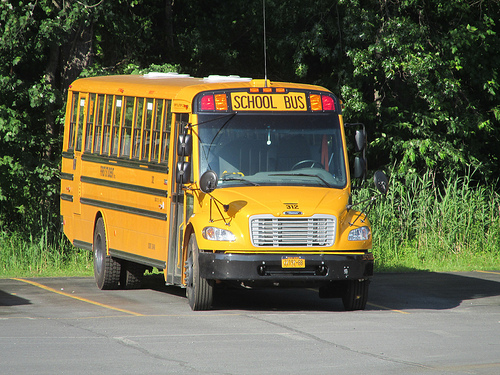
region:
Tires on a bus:
[84, 198, 142, 314]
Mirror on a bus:
[183, 161, 258, 227]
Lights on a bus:
[192, 78, 237, 126]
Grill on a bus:
[241, 203, 346, 263]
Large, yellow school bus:
[52, 65, 408, 324]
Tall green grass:
[358, 172, 494, 285]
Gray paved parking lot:
[34, 277, 249, 368]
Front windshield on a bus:
[193, 92, 374, 205]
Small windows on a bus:
[59, 76, 180, 171]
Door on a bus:
[163, 104, 203, 277]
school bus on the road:
[56, 60, 386, 317]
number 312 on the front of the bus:
[284, 202, 306, 212]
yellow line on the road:
[7, 272, 151, 324]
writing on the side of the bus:
[98, 160, 125, 180]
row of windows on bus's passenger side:
[67, 88, 177, 169]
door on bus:
[171, 108, 193, 291]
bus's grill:
[251, 209, 339, 251]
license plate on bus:
[278, 252, 308, 272]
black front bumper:
[195, 247, 379, 292]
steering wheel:
[289, 155, 325, 172]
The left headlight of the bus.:
[204, 223, 238, 245]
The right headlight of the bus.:
[344, 225, 372, 244]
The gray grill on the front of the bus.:
[247, 215, 336, 248]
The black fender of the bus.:
[202, 247, 373, 282]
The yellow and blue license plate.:
[280, 255, 305, 267]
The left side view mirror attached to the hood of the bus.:
[200, 163, 235, 218]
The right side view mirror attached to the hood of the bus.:
[357, 160, 390, 230]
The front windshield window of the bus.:
[195, 111, 343, 188]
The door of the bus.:
[167, 113, 192, 291]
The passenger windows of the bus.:
[72, 90, 174, 166]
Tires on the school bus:
[183, 233, 213, 299]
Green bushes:
[405, 178, 481, 230]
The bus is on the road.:
[131, 303, 276, 365]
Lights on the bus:
[197, 221, 237, 243]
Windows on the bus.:
[103, 115, 136, 158]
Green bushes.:
[370, 43, 482, 134]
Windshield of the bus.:
[216, 125, 286, 157]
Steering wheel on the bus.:
[292, 161, 338, 175]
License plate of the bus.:
[275, 251, 320, 269]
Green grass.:
[7, 226, 68, 265]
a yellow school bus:
[43, 43, 400, 327]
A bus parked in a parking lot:
[41, 63, 498, 363]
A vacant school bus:
[26, 24, 498, 372]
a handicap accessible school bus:
[42, 47, 462, 372]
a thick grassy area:
[375, 4, 498, 300]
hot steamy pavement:
[293, 305, 496, 371]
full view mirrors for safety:
[166, 70, 401, 320]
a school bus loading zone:
[2, 107, 215, 370]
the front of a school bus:
[188, 174, 382, 305]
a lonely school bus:
[41, 39, 427, 338]